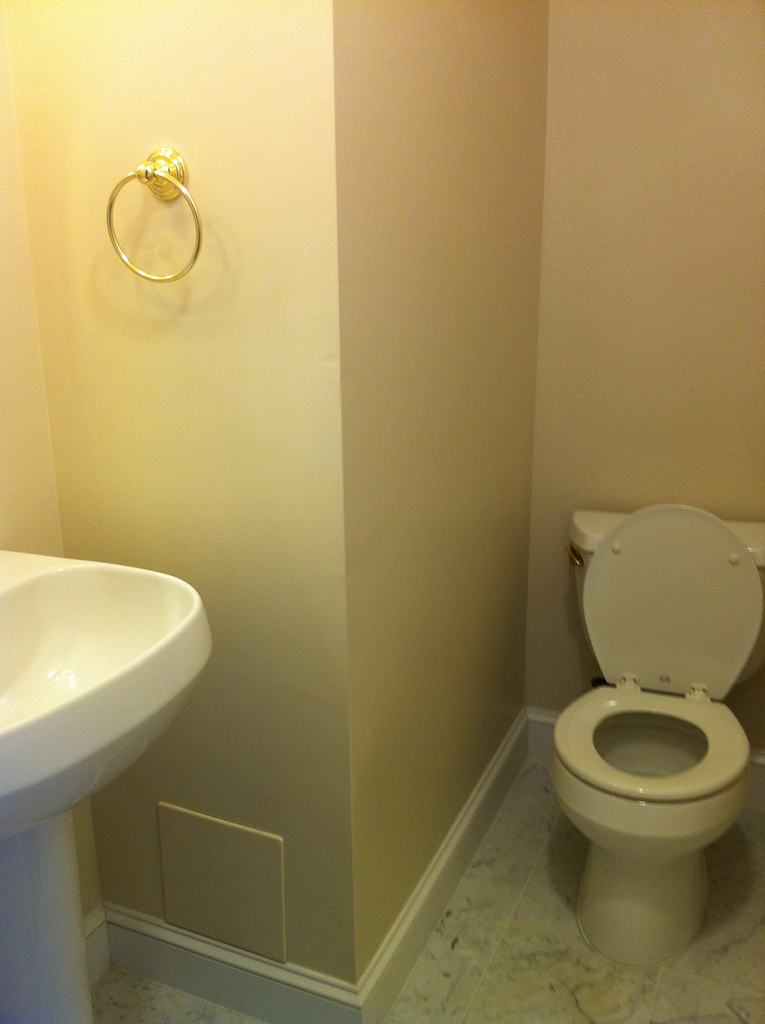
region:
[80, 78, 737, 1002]
this is a bathroom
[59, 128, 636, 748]
the bathroom is empty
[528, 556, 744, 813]
this is a toilet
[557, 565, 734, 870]
the toilet is white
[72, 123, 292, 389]
this is a hook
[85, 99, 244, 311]
the hook is metal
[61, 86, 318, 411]
the hook is silver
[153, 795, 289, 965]
emergency access door for electrical or piping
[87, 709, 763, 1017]
beautifully designed marble tile flooring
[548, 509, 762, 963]
new, clean porclien toilet with plastic seat ring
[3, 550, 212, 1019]
new ,clean porclien bathroom sink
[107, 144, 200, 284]
Polished bass ring for hanging a hand towel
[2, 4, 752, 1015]
breige colored walls with white dust boards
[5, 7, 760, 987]
beige painted walls with brass hand towel holder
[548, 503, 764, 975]
sanitized porclein pot with plastic seat and lid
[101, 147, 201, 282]
A gold round towel holder.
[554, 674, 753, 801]
A white toilet seat.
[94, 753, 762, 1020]
A marbled mostly white floor.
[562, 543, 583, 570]
A gold toilet flusher.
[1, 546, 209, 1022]
A tall white sink.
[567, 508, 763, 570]
White toilet tank lid.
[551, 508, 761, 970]
A white toilet with gold flusher.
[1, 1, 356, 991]
Beige wall with a towel holder on it.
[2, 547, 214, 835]
A white sink top.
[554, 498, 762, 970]
toilet in bathroom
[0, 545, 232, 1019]
sink in bathroom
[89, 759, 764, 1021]
white and grey tile in bathroom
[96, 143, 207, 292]
towel ring on wall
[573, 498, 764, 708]
white toilet lid in bathroom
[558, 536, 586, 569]
silver fush lever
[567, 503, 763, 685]
toilet tank behind toilet lid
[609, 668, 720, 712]
hinges at toilet lid base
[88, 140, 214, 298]
a gold holder on a wall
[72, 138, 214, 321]
a gold towel holder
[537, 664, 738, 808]
the seat is white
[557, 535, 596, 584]
the handle is silver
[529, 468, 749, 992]
a open toilet seat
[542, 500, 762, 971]
toilet in a bathroom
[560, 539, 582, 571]
handle to flush the water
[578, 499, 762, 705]
toilet seat lid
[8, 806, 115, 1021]
base of bathroom sink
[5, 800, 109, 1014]
base of bathroom sink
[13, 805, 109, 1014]
base of bathroom sink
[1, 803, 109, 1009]
base of bathroom sink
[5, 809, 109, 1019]
base of bathroom sink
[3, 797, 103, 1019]
base of bathroom sink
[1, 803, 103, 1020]
base of bathroom sink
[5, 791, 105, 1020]
base of bathroom sink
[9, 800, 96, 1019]
base of bathroom sink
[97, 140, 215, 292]
brass towel ring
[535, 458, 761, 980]
open white toilet with deat down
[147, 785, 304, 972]
painted access panel cover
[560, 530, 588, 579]
silver toilet flush handle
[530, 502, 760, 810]
white toilet seat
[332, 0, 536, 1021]
brown wall with white baseboard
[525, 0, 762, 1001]
brown wall white white baseboard behind a toilet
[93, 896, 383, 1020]
white wooden baseboard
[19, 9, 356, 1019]
brown wall with access panel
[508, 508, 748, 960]
a toilet in the bathroom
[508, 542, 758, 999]
a white toilet in the bathroom